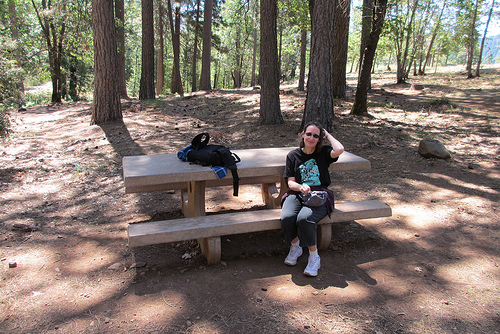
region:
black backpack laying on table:
[172, 126, 251, 192]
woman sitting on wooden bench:
[275, 107, 376, 292]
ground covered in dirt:
[47, 270, 193, 332]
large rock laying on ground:
[405, 124, 468, 181]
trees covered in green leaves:
[214, 7, 261, 89]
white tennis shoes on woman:
[272, 239, 337, 286]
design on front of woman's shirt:
[297, 156, 327, 188]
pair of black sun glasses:
[300, 122, 321, 147]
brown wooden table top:
[116, 147, 182, 186]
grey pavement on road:
[21, 68, 57, 102]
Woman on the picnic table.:
[121, 113, 441, 315]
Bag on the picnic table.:
[161, 106, 267, 182]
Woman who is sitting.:
[278, 118, 395, 280]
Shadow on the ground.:
[265, 240, 410, 302]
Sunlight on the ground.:
[226, 252, 405, 332]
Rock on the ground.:
[411, 139, 466, 171]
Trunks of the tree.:
[76, 11, 376, 158]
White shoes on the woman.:
[234, 235, 439, 326]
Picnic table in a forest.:
[68, 122, 490, 291]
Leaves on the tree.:
[26, 17, 108, 121]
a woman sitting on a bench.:
[245, 100, 362, 286]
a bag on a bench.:
[148, 106, 255, 198]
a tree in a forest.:
[68, 0, 138, 144]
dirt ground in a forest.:
[2, 57, 494, 332]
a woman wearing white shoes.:
[272, 118, 357, 281]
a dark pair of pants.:
[270, 183, 335, 253]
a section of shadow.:
[405, 220, 473, 282]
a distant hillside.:
[478, 41, 498, 68]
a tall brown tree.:
[293, 1, 340, 128]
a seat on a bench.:
[123, 189, 402, 294]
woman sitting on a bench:
[261, 113, 361, 279]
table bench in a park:
[118, 138, 178, 264]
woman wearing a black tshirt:
[276, 108, 351, 254]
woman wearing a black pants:
[276, 111, 356, 294]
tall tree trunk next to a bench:
[76, 10, 147, 133]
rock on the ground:
[415, 123, 461, 194]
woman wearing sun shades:
[265, 111, 355, 276]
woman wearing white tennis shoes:
[265, 101, 350, 286]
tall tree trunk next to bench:
[298, 10, 349, 125]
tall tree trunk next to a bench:
[253, 8, 305, 120]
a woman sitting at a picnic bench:
[112, 111, 399, 297]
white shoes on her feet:
[278, 243, 349, 304]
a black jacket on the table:
[177, 124, 254, 194]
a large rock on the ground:
[413, 132, 457, 173]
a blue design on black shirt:
[297, 155, 329, 189]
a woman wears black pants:
[273, 133, 350, 283]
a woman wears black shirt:
[273, 112, 365, 299]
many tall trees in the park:
[12, 0, 489, 133]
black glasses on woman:
[305, 127, 317, 141]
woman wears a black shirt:
[278, 131, 353, 206]